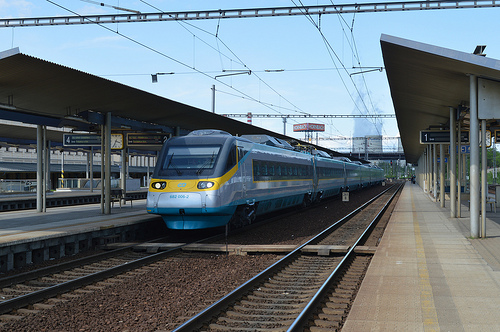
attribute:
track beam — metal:
[120, 237, 376, 255]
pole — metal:
[57, 153, 68, 193]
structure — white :
[224, 102, 274, 137]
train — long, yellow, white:
[145, 128, 385, 230]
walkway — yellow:
[341, 173, 491, 331]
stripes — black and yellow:
[53, 173, 73, 196]